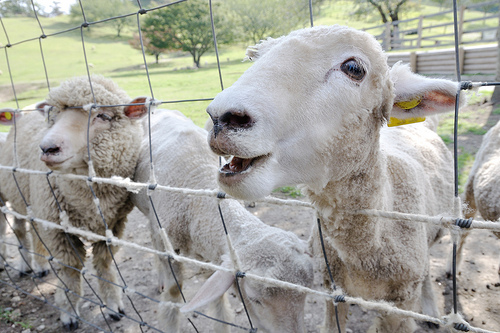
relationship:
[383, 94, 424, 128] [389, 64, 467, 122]
tag in sheep's ear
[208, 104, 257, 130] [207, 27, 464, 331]
nose of sheep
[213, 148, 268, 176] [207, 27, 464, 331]
mouth of sheep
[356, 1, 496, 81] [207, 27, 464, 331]
fence behind sheep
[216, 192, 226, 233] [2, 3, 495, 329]
line on wire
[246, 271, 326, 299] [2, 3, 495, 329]
covering on wire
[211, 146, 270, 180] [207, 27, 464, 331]
mouth of sheep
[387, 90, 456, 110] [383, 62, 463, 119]
inside of ears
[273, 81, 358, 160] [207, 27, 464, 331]
wool on sheep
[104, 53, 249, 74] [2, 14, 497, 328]
shadow cast on ground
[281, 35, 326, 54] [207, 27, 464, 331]
bump on front sheep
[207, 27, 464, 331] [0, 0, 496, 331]
sheep in pen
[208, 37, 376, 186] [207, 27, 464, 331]
face of sheep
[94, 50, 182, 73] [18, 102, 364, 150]
trees in background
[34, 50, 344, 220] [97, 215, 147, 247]
two sheep looking at camera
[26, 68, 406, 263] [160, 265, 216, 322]
sheep behind a fence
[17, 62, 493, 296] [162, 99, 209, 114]
animals in a pen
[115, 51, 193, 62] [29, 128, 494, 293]
trees are in background